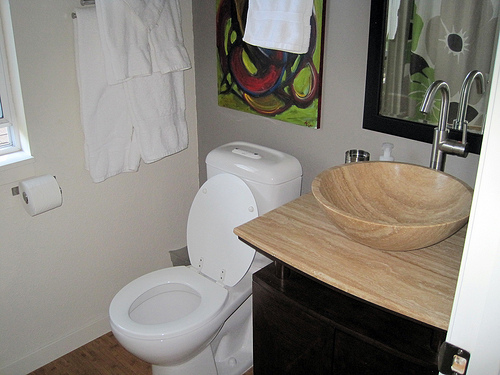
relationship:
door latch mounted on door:
[434, 339, 470, 373] [436, 33, 484, 373]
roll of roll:
[19, 174, 65, 213] [19, 174, 63, 217]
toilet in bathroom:
[108, 224, 238, 367] [14, 3, 498, 373]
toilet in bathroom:
[108, 141, 303, 375] [14, 3, 498, 373]